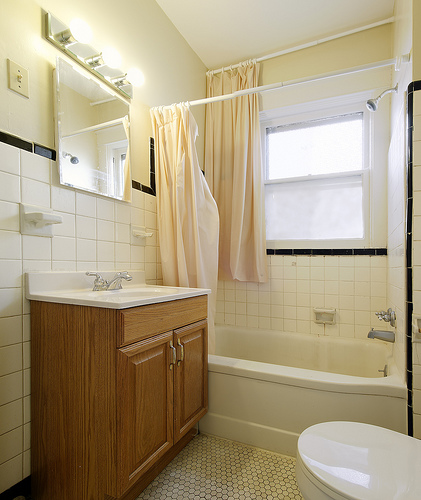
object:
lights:
[44, 9, 146, 99]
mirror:
[53, 53, 132, 204]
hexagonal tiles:
[248, 431, 299, 497]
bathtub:
[197, 321, 414, 457]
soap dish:
[314, 307, 338, 331]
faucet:
[361, 323, 398, 344]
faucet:
[84, 269, 111, 289]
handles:
[87, 270, 105, 279]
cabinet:
[100, 299, 174, 476]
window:
[259, 110, 364, 245]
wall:
[235, 29, 383, 243]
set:
[297, 420, 415, 498]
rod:
[149, 63, 419, 115]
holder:
[14, 199, 65, 241]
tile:
[1, 198, 21, 232]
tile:
[2, 229, 24, 260]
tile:
[23, 234, 52, 262]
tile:
[49, 234, 79, 262]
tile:
[53, 206, 80, 237]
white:
[348, 449, 379, 479]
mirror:
[47, 51, 136, 206]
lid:
[296, 419, 419, 498]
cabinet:
[50, 52, 148, 201]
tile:
[227, 455, 240, 492]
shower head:
[61, 149, 80, 163]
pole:
[198, 61, 391, 108]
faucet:
[107, 267, 133, 292]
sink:
[24, 259, 208, 312]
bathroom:
[4, 3, 420, 499]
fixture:
[43, 12, 147, 98]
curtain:
[151, 94, 226, 287]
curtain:
[199, 60, 271, 288]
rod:
[202, 16, 402, 77]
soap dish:
[13, 200, 60, 237]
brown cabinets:
[31, 293, 208, 498]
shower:
[361, 83, 398, 113]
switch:
[6, 55, 31, 97]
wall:
[2, 0, 199, 283]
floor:
[121, 430, 214, 498]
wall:
[35, 180, 172, 269]